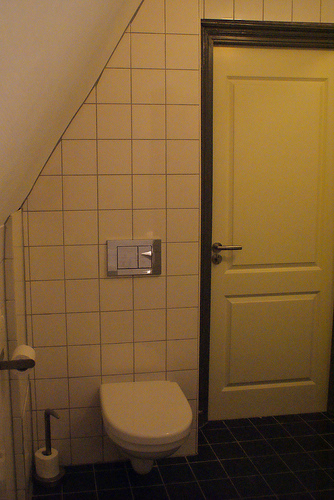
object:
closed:
[99, 371, 195, 458]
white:
[30, 350, 35, 358]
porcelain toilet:
[99, 376, 196, 477]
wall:
[19, 0, 206, 469]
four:
[101, 306, 165, 376]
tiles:
[66, 313, 100, 346]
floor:
[32, 410, 334, 500]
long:
[210, 241, 246, 255]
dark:
[202, 61, 212, 94]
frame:
[197, 17, 334, 443]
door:
[207, 42, 334, 426]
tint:
[260, 339, 287, 353]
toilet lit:
[98, 380, 193, 446]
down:
[146, 388, 191, 448]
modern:
[86, 343, 201, 477]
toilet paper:
[33, 445, 61, 481]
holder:
[32, 408, 64, 486]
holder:
[0, 348, 35, 372]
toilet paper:
[9, 343, 36, 415]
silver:
[108, 238, 162, 278]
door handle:
[216, 242, 245, 252]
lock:
[212, 253, 222, 265]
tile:
[189, 459, 228, 481]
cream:
[37, 313, 196, 380]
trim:
[197, 17, 214, 437]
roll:
[12, 344, 36, 377]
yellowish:
[262, 203, 302, 255]